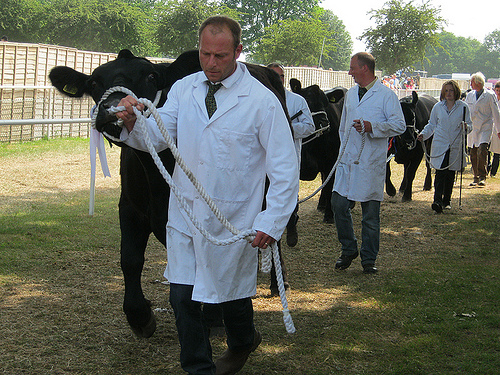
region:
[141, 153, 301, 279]
a white rope in the mans hand looks very soft and nice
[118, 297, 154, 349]
the cows foot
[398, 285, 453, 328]
grass on the ground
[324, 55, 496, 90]
heads of the people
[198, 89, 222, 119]
a tie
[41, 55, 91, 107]
cows ear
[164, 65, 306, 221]
a white jacket on the man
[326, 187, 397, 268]
blue jeans on the man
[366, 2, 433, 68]
a tree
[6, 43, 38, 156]
a fence in the back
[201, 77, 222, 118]
Man wearing a black tie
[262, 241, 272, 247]
Wedding ring on a man's left hand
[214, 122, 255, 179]
Pocket on man's white jacket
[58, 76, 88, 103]
Yellow tag on a cow's ear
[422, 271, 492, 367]
Green grass on the ground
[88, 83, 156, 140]
White rope around a cow's nose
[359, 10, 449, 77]
Tree behind a fence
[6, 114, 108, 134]
White rail in front of fence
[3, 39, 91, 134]
Wooden fence in front of trees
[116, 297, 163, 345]
Black cow hoof off the ground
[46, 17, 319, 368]
A man next to a black cow.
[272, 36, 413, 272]
Two men are standing behind the man at the front of the line.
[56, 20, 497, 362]
A line of people with a line of cows.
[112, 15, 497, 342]
The people are wearing white coats.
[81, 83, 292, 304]
The man is pulling the cow along with a rope.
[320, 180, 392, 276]
The man is wearing pants.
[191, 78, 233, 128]
The man is wearing a tie.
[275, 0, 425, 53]
Trees in the background.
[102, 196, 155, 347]
The leg of a cow.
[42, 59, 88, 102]
The ear of a cow.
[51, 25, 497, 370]
a line of people walking with cows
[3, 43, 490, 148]
a long fence along the side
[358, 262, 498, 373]
some green grass in the corner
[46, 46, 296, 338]
a big black cow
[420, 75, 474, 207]
a woman standing next to the cow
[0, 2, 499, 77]
a bunch of trees behind the fence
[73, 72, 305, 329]
the rope holding onto the cow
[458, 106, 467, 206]
the stick the woman is holding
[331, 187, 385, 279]
the jeans the man is wearing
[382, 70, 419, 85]
people standing by the fence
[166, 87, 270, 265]
The lab gown is white.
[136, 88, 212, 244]
The lab gown is white.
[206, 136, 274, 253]
The lab gown is white.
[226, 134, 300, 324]
The lab gown is white.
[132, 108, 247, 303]
The lab gown is white.